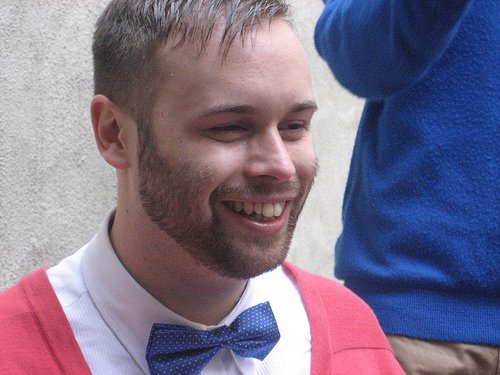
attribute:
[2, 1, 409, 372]
man — smiling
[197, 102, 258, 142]
eye — squinted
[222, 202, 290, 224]
teeth — inside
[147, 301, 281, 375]
bow tie — blue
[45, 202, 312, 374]
shirt — white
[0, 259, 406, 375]
sweater — red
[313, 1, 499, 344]
sweater — bright blue, blue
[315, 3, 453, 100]
elbow — bent